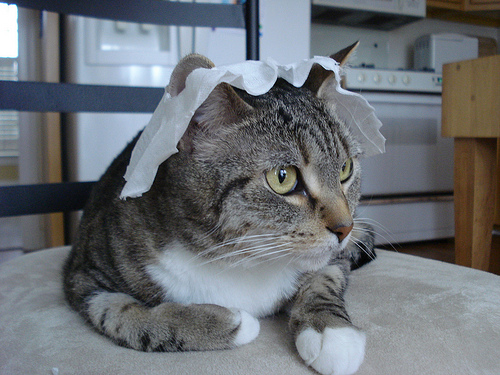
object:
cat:
[61, 41, 379, 374]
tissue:
[116, 55, 389, 201]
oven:
[335, 89, 459, 195]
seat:
[0, 239, 499, 375]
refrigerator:
[69, 5, 247, 178]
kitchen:
[1, 3, 500, 258]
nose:
[325, 212, 357, 244]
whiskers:
[191, 233, 278, 263]